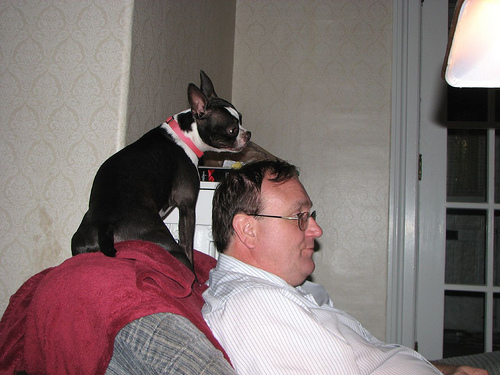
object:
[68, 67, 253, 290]
dog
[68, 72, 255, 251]
fur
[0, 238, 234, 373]
blanket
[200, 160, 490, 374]
man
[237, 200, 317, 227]
glasses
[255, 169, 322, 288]
face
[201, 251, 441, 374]
shirt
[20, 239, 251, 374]
chair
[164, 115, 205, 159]
collar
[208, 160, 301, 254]
hair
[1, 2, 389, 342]
wall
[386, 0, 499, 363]
door frame